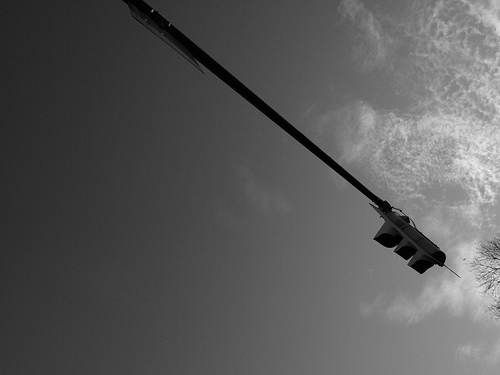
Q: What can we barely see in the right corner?
A: Tree.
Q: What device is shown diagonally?
A: Traffic signal.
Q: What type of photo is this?
A: Black and White.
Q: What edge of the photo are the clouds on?
A: Right.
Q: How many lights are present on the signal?
A: Three.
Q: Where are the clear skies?
A: On half of the scene.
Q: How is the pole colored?
A: Black.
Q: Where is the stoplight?
A: In the photo.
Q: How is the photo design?
A: A black and white.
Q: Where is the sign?
A: Attached to the stop light.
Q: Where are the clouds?
A: In the sky.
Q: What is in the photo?
A: A stoplight.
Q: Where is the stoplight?
A: Next to branches.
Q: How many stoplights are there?
A: One.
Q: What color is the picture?
A: Black and white.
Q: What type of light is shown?
A: A traffic light.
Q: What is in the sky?
A: Clouds.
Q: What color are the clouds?
A: White.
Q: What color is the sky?
A: Grey.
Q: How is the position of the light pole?
A: Upside down.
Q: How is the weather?
A: Clear.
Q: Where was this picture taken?
A: A city street.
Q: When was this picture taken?
A: Afternoon.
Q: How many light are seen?
A: Three.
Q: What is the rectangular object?
A: Traffic light.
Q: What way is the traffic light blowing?
A: Backwards.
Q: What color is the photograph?
A: Black and white.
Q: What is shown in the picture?
A: A light post.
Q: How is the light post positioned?
A: It is leaning.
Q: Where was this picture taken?
A: At the street corner.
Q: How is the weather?
A: Overcast.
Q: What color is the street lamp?
A: Black.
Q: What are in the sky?
A: Clouds.